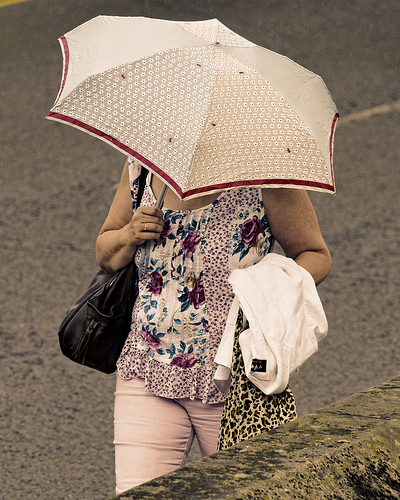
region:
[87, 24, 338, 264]
a woman holding a umbrella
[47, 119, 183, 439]
a woman carrying a black purse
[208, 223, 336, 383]
a woman carrying a white shirt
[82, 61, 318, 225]
a pink umbrella with flower design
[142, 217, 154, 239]
a woman wearing a ring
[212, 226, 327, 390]
a woman with clothing over her arm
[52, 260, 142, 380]
a black purse with zippers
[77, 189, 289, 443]
a woman wearing a shirt with a floral print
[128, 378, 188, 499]
a woman wearing pink pants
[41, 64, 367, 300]
a woman under a umbrella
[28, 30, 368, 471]
a woman with an umbrella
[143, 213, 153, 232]
a ring on her ring finger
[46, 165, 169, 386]
a black bag over the shoulder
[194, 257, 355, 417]
a white jacket in hand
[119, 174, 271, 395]
a blouse with flowers on it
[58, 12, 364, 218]
a red beige and white umbrella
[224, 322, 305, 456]
a leppard print material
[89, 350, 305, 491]
pink pants on woman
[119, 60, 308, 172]
several red spots on umbrella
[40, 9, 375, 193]
an open umbrella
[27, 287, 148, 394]
black purse on woman's side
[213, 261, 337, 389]
white coat over woman's arm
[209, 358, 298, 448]
cheetah print coat over arm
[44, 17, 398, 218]
open umbrella held by woman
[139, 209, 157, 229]
wedding ring on finger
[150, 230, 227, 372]
floral pattern on blouse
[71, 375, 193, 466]
khaki pants on woman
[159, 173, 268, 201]
red line around umbrella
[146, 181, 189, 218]
metal pole of umbrella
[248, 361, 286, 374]
black tag on white clothing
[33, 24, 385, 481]
lady carrying an umbrella in the rain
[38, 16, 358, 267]
lady carrying an umbrella in the rain hiding her face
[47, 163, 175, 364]
black purse on the ladys shoulder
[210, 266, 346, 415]
white sweater on the ladys arm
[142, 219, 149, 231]
gold ring on lady's finger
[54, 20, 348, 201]
umbrella with flower design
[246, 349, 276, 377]
tag on a white sweater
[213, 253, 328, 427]
clothing draped over woman's arm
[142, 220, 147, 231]
small ring on woman's right ring finger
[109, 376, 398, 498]
cement retaining wall along sidewalk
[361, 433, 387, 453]
green moss growing on wall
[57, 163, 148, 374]
black purse draped over woman's shoulder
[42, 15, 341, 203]
woman's face is covered by umbrella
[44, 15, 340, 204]
umbrella with flower design on it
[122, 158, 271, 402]
tank top blouse with flower design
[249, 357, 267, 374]
black tag inside white shirt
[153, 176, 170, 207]
silver umbrella handle being held by woman